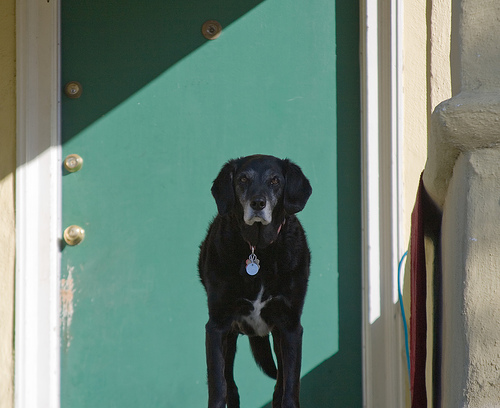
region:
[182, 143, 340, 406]
an old black and white dog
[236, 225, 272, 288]
a blue metal dog tag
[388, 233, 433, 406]
a long blue wire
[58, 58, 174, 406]
an ugly green door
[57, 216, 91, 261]
a gold colored door knob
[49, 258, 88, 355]
scratch marks on a door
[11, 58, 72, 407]
thick white crown molding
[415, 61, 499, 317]
a tan concrete support beam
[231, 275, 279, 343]
white stripes on a dog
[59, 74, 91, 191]
two dead bolt locks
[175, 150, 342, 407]
dog standing in front of a door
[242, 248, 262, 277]
tag and license on dog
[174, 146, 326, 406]
dog with white underbelly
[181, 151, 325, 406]
dog with black hair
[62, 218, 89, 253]
bronze colored door knob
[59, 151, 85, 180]
bronze colored deadbolt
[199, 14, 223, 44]
peep hole on a door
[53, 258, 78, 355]
faded paint on a door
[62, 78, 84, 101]
deadbolt on a door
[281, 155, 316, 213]
ear of a dog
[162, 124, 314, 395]
the dog is black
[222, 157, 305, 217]
the eyes are brown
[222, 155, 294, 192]
the eyes are open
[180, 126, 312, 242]
the dog is looking at the camera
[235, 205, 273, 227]
the mouth is grey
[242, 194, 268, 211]
the nose is black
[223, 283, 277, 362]
the stomach is white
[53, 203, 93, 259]
the door knob is gold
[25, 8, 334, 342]
the door is green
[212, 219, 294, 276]
the dog is wearing a collar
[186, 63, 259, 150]
part of a wall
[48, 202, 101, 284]
part of al=knob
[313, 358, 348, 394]
part of a shade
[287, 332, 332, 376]
edge of a shade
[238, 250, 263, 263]
part of a necklace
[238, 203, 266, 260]
part of a mouth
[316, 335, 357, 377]
part of a shade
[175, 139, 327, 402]
a black dog inside a home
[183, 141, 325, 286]
black dog looks mad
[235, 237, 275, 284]
pendants on collar of dog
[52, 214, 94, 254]
a yellow door knob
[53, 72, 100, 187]
door has two locks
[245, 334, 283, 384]
tail of dog is black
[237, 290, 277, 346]
white part of dog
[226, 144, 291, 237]
face of dog is white and black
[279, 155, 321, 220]
right ear of dog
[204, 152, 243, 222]
left ear of dog